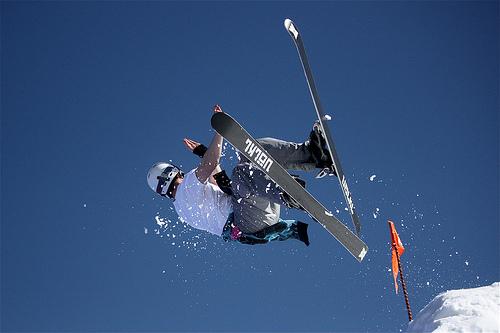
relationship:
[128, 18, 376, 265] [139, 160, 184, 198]
skier with helmet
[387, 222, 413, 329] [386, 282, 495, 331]
flag in snow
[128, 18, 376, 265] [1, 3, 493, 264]
skier in air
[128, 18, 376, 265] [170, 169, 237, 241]
skier wearing shirt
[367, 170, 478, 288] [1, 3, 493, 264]
snow in air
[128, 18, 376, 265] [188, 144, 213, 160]
skier wearing gloves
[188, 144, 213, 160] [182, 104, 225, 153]
gloves on hands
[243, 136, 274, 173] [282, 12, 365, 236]
lettering on ski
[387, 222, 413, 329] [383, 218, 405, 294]
flag on orange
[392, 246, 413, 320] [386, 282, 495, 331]
pole in snow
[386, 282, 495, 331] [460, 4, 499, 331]
snow on right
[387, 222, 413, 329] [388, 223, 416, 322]
flag on rod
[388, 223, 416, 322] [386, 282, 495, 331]
rod in snow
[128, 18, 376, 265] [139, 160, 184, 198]
skier wearing helmet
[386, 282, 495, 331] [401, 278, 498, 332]
snow in pile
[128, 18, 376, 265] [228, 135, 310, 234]
skier wearing pants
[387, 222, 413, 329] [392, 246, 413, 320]
flag on pole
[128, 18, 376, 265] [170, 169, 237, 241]
skier wearing tshirt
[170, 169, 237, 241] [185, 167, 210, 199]
tshirt has short sleeves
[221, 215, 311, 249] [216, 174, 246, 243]
jacket around waist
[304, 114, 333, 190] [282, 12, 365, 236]
foot attached to ski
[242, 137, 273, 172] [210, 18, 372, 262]
logo on bottom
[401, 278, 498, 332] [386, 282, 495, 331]
mound of snow